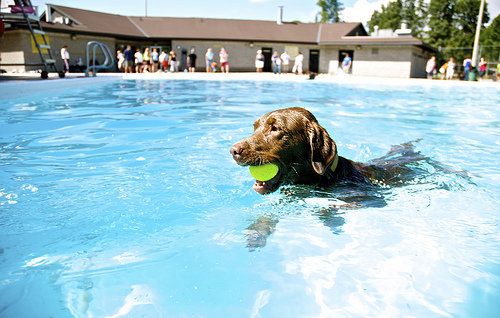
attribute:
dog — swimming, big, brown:
[216, 99, 467, 246]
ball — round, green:
[244, 157, 285, 185]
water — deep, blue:
[3, 71, 499, 313]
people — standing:
[114, 41, 313, 78]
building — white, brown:
[29, 0, 494, 28]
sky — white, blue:
[4, 4, 430, 80]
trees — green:
[317, 0, 499, 62]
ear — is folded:
[307, 119, 339, 170]